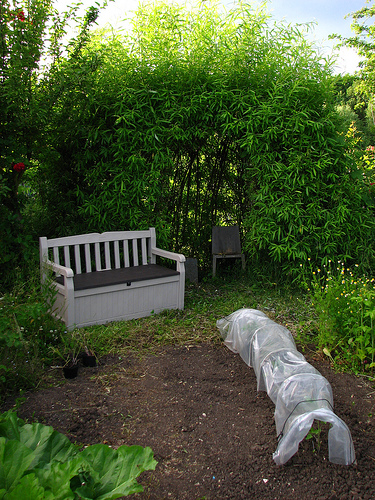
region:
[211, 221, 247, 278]
a brown chair under tree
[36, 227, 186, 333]
a bench with storage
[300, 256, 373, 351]
a plant with small flowers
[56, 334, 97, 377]
two pots of plants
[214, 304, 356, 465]
plastic protective covering for plants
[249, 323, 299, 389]
silver metal hoops visible under plastic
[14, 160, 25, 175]
a red flower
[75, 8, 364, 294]
a large green bush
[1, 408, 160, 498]
large green leaves in the freground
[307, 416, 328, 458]
a plant is growing under the plastic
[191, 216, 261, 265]
there is a chair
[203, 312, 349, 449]
item wrapped in tarp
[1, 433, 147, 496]
large leaves on side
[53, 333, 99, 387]
there are two plants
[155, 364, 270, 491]
the ground has gravel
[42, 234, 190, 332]
there is a white bench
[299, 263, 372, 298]
small yellow flowers growing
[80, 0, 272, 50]
sun shining on tree top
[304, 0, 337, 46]
the sky is cloudy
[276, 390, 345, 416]
there is a green tie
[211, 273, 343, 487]
some kind of greenhouse thing set up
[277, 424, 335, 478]
plant growing in the greenhouse thing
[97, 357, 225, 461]
dirt surrounding the greenhouse thing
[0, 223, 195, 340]
bench in the woody area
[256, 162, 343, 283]
leaves on the trees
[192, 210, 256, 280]
rocking chair in the woody area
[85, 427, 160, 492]
plant leaf growing in the ground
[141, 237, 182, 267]
arm rest of the bench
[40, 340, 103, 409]
plants that just came lout of their pots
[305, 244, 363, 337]
flowers growing in the grass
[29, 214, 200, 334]
a wooden bench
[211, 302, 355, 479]
plastic over the plants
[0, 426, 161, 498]
green leaves in left bottom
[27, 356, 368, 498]
black dirt on ground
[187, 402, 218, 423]
something white in dirt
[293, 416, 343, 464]
green plant showing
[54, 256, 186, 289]
draker brown lid on bench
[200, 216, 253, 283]
old chair to right of bench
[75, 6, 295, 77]
sunlight at tops of trees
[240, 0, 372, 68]
blue sky shows through tres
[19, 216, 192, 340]
a wooden bench with a brown cushion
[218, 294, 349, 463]
a row of plants covered with plastic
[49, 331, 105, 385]
two plants in pots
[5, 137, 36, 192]
a red flower in a tree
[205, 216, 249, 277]
a brown metal chair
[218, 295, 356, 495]
a long piece of plastic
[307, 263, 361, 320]
a patch of yellow flowers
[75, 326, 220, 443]
a patch of dirt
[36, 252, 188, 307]
a brown cushion on a bench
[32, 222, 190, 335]
a tan bench with a cushion